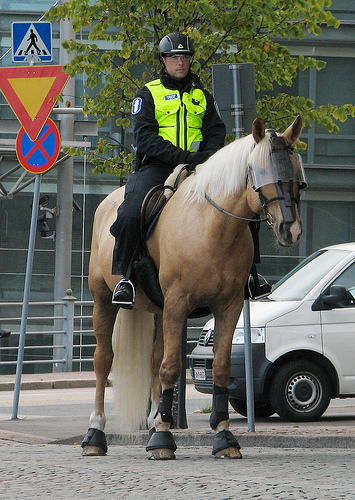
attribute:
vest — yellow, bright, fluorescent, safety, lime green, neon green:
[141, 75, 203, 168]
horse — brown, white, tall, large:
[80, 112, 309, 462]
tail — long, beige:
[111, 303, 153, 440]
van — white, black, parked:
[186, 240, 355, 423]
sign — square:
[10, 17, 57, 60]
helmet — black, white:
[155, 30, 198, 58]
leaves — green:
[41, 3, 354, 181]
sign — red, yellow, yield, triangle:
[0, 61, 72, 139]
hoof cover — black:
[212, 426, 242, 455]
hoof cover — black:
[144, 426, 185, 451]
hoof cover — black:
[77, 424, 110, 450]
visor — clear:
[245, 149, 310, 188]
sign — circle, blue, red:
[15, 117, 62, 173]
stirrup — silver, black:
[113, 276, 138, 307]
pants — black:
[114, 162, 266, 282]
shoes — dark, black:
[114, 281, 134, 310]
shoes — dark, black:
[244, 269, 277, 300]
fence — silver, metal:
[8, 296, 209, 371]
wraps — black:
[258, 191, 305, 246]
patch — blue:
[129, 94, 146, 119]